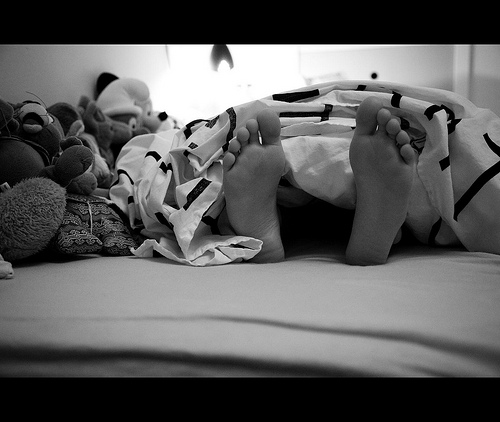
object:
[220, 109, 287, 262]
feet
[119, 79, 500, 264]
blanket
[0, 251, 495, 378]
sheets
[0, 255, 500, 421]
bed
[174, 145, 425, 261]
person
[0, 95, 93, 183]
animals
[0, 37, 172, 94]
wall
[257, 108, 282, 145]
toes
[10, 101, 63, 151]
face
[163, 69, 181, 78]
light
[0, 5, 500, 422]
room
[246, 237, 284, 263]
heel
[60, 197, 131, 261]
items